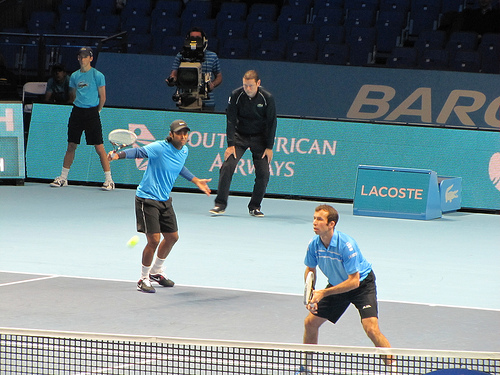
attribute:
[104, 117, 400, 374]
people — playing tennis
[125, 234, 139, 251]
ball — in the air, yellow, green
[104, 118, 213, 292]
man — standing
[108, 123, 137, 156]
racket — white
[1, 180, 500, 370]
court — gray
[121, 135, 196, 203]
shirt — blue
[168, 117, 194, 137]
hat — black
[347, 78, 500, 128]
word — in the background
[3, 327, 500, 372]
net — black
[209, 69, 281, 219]
man — slightly crouched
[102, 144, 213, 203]
man's arms — outstretched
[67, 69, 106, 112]
man's arms — behind his back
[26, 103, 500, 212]
sign — blue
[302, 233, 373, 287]
shirt — blue, striped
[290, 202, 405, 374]
man — bending over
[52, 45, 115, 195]
referee — standing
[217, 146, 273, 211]
pants — black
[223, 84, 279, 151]
shirt — black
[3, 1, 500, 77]
seats — empty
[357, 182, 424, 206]
letters — white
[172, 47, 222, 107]
shirt — blue